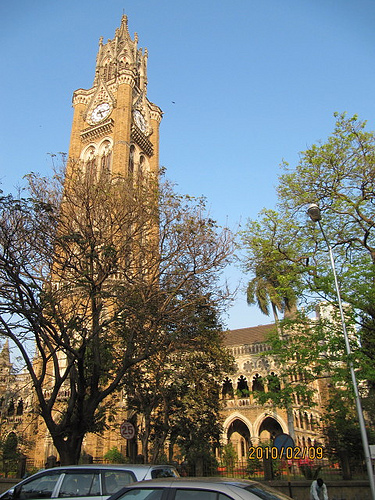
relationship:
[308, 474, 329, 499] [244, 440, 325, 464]
man below date stamp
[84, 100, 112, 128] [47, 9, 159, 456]
clock on tower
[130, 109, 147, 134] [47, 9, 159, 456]
clock on tower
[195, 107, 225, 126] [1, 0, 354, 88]
clouds in sky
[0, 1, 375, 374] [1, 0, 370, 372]
clouds in sky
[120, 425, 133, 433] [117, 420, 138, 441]
number on sign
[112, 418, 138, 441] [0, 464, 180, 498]
sign beside hatchback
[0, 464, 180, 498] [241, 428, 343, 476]
hatchback beside sign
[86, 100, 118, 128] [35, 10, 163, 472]
clock on building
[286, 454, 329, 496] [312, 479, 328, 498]
man wearing shirt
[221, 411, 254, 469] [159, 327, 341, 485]
arches on building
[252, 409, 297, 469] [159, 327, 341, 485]
arches on building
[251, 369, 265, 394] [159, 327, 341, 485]
arches on building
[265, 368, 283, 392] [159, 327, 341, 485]
arches on building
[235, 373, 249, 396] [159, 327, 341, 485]
arches on building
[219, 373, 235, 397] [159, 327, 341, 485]
arches on building